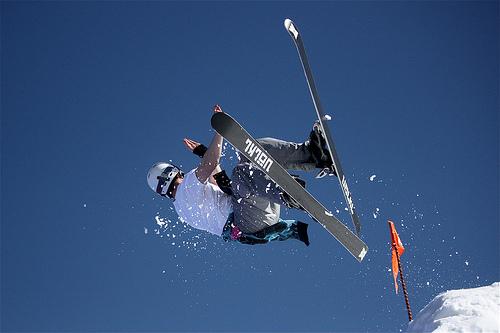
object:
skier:
[143, 102, 341, 245]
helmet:
[145, 160, 184, 198]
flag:
[387, 222, 413, 329]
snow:
[399, 282, 499, 332]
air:
[1, 3, 499, 331]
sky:
[1, 1, 498, 332]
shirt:
[170, 169, 237, 241]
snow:
[367, 170, 478, 288]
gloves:
[192, 144, 212, 159]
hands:
[182, 137, 209, 153]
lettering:
[243, 136, 274, 173]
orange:
[383, 218, 405, 294]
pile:
[401, 278, 498, 332]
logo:
[242, 137, 273, 172]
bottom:
[210, 18, 372, 262]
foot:
[304, 119, 333, 180]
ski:
[282, 12, 365, 236]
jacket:
[221, 215, 311, 249]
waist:
[202, 185, 237, 239]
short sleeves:
[185, 167, 210, 199]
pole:
[387, 220, 414, 320]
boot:
[307, 122, 334, 180]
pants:
[228, 135, 310, 234]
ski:
[210, 109, 370, 264]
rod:
[388, 223, 416, 322]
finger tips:
[182, 139, 194, 153]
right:
[460, 4, 499, 331]